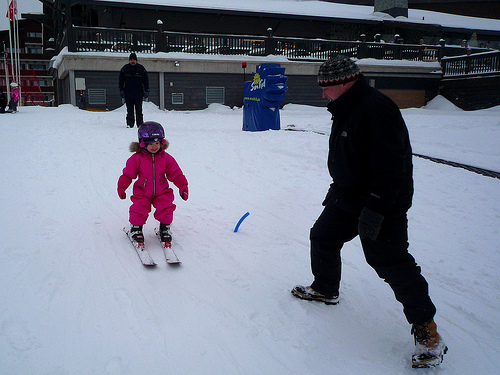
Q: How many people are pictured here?
A: Four.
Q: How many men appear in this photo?
A: Two.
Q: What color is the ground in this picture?
A: White.